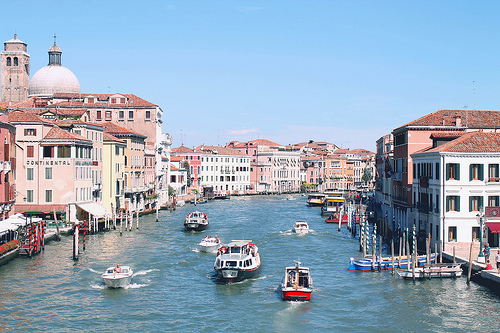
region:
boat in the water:
[396, 248, 464, 290]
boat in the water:
[320, 198, 367, 228]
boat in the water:
[282, 200, 322, 235]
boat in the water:
[273, 252, 330, 312]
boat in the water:
[205, 230, 261, 295]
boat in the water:
[175, 197, 221, 247]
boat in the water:
[195, 221, 220, 254]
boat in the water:
[92, 257, 152, 302]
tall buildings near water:
[20, 86, 175, 221]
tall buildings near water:
[373, 97, 496, 228]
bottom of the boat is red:
[282, 285, 319, 310]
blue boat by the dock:
[348, 252, 438, 269]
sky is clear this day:
[172, 38, 407, 108]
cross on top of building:
[43, 31, 59, 46]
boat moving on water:
[94, 260, 154, 311]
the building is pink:
[27, 170, 87, 197]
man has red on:
[105, 258, 128, 288]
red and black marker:
[11, 214, 63, 263]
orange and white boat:
[301, 187, 329, 217]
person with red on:
[475, 254, 495, 274]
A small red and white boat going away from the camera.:
[280, 256, 315, 302]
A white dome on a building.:
[27, 63, 80, 96]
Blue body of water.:
[3, 187, 491, 329]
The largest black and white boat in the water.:
[213, 238, 261, 281]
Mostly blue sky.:
[1, 0, 498, 137]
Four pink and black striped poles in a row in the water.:
[23, 220, 45, 251]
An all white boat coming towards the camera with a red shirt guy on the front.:
[103, 261, 133, 285]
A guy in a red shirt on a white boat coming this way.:
[113, 263, 123, 274]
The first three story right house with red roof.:
[404, 130, 499, 249]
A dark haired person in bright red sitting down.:
[483, 258, 492, 269]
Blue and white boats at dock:
[344, 218, 475, 285]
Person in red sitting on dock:
[419, 194, 498, 311]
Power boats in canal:
[180, 184, 329, 321]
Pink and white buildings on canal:
[89, 144, 377, 219]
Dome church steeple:
[29, 28, 86, 99]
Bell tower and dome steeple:
[1, 21, 98, 112]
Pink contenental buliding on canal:
[0, 105, 147, 260]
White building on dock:
[408, 141, 495, 292]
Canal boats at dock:
[311, 177, 465, 285]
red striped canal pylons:
[1, 203, 101, 287]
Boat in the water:
[268, 254, 316, 306]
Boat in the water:
[93, 263, 142, 292]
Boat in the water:
[178, 203, 211, 235]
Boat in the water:
[193, 230, 222, 254]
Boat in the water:
[213, 235, 262, 291]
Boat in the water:
[280, 214, 319, 239]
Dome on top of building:
[28, 33, 90, 95]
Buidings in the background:
[166, 134, 376, 204]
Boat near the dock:
[346, 246, 456, 278]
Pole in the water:
[67, 215, 86, 265]